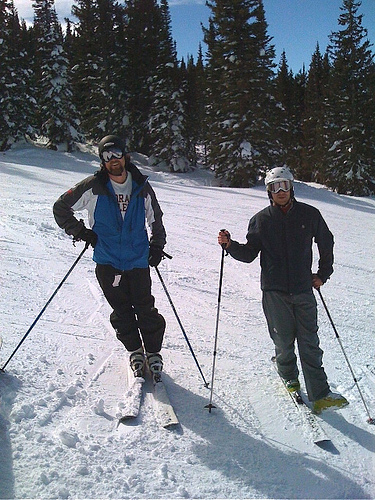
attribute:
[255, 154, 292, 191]
helmet — white, grey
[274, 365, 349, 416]
boots — yellow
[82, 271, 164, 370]
pants — black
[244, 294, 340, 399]
pants — grey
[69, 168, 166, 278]
jacket — white, black, blue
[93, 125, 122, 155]
helmet — black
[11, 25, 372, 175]
trees — in background, green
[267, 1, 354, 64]
sky — blue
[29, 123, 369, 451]
people — skiing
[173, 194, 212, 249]
snow — trampled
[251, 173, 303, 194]
goggles — covering eyes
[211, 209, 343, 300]
jacket — black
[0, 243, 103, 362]
pole — angled